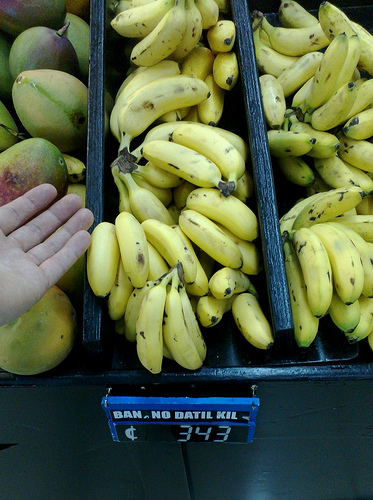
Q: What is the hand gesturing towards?
A: Bananas.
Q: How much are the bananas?
A: 343.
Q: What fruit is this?
A: Bananas.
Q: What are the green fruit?
A: Mangoes.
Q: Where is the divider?
A: Between the fruits.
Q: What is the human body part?
A: A hand.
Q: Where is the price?
A: On the sign.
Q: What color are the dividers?
A: Black.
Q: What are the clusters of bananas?
A: Bunches.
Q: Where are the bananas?
A: In a food bin.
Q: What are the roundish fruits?
A: Mangoes.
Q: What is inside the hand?
A: A palm.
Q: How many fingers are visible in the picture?
A: Four.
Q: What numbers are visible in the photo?
A: 343.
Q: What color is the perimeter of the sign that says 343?
A: Blue.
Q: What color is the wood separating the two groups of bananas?
A: Black.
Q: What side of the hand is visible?
A: Palm side.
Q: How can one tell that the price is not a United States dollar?
A: Currency symbol.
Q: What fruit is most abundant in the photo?
A: Bananas.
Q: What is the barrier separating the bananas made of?
A: Wood.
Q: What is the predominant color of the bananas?
A: Yellow.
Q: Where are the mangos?
A: Left side of the photo.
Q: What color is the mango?
A: Green.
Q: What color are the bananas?
A: Yellow.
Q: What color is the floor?
A: Gray.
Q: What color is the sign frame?
A: Blue.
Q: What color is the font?
A: White.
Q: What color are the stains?
A: Black.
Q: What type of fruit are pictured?
A: Mangoes and bananas.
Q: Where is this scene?
A: At a grocery store.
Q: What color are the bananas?
A: Yellow.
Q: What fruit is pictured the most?
A: Bananas.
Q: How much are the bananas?
A: 343.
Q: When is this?
A: Daytime.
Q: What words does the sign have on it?
A: Ban no datil kil.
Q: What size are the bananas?
A: Small.